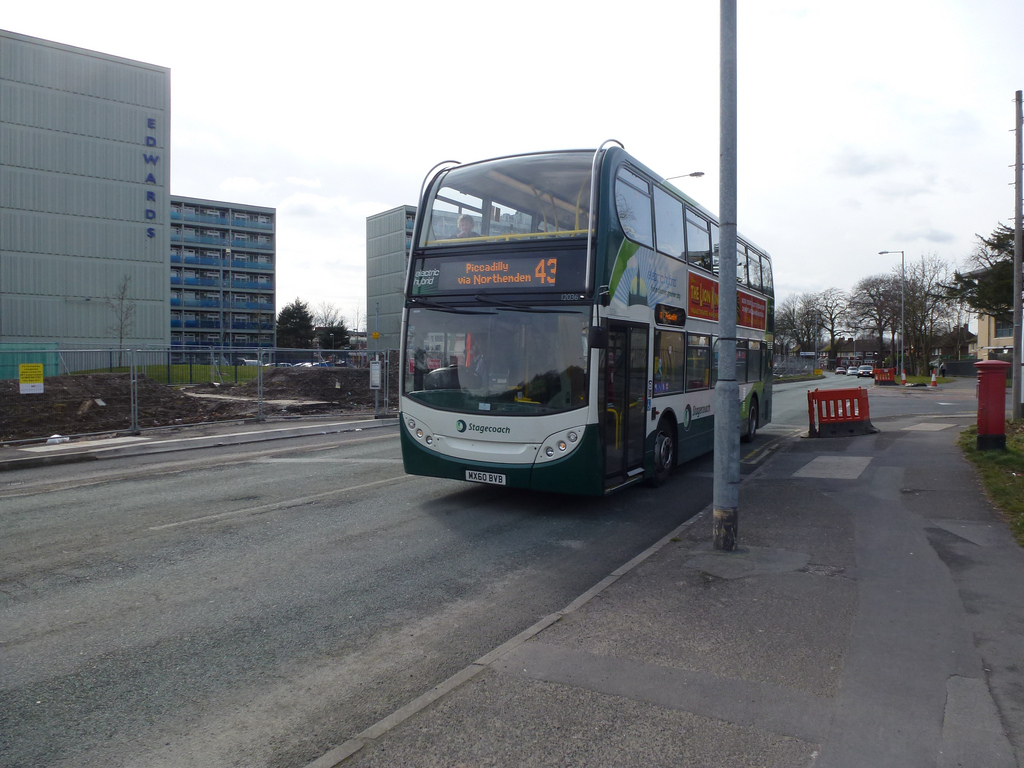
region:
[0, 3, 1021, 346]
cloud cover in sky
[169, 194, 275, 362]
building with blue balconies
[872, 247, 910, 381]
light on curved pole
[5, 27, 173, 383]
vertical word on wall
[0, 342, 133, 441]
sign on chain link fence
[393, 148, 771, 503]
front corner of double decker bus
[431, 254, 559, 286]
characters on digital display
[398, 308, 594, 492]
windshield on front of bus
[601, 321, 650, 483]
closed door of bus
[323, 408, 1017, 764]
surface of city sidewalk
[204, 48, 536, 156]
Sky is white color.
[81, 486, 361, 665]
Road is grey color.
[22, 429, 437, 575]
White lines in road.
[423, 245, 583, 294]
Letters are orange in color.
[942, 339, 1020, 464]
Pillar is red color.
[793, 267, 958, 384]
Trees are without leaves.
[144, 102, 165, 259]
Letters are blue color.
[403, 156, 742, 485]
Bus is green and white color.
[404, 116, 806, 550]
double deck passenger bus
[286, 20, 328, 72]
white clouds in blue sky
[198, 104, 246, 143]
white clouds in blue sky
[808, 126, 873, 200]
white clouds in blue sky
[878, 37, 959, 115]
white clouds in blue sky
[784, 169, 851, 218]
white clouds in blue sky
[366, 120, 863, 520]
Bus on the street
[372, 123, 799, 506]
Bus on the road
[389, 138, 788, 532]
Bus near the sidewalk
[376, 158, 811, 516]
Bus near the curb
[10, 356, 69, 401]
Sign on the fence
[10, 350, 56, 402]
Yellow sign on fence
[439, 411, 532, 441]
Writing on the bus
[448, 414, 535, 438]
Letters on the bus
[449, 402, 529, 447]
Letters on front of bus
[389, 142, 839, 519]
a bus that is white and green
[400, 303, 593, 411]
the windshield of a bus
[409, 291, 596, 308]
the wipers of a bus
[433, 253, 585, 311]
the sign of a bus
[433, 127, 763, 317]
the second story of a bus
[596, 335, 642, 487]
the door of a bus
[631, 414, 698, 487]
the front wheel of a bus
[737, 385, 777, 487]
the back wheel of a bus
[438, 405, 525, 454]
the logo of a bus